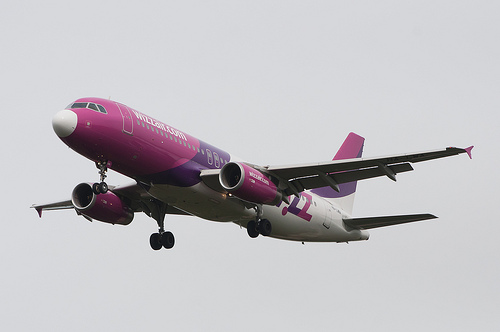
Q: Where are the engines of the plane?
A: Attached, below either of the plane's wings.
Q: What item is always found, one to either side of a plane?
A: The plane's wings.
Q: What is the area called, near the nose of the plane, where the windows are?
A: The cockpit.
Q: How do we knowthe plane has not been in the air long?
A: The landing gear is not retracted.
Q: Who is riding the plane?
A: Passengers and flight crew.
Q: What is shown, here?
A: A purple and white, passenger plane.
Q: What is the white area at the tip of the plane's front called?
A: The nose.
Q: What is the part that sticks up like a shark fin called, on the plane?
A: The tail.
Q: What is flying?
A: Plane.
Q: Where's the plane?
A: Mid air.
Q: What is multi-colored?
A: Plane.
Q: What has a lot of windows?
A: Plane.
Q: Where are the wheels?
A: Under plane.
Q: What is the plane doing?
A: Flying.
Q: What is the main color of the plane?
A: Purple.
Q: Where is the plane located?
A: In the air.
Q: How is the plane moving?
A: It is flying.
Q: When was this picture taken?
A: Daytime.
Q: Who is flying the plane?
A: Pilot.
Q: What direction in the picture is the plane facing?
A: Left.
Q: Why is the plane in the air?
A: It is flying.